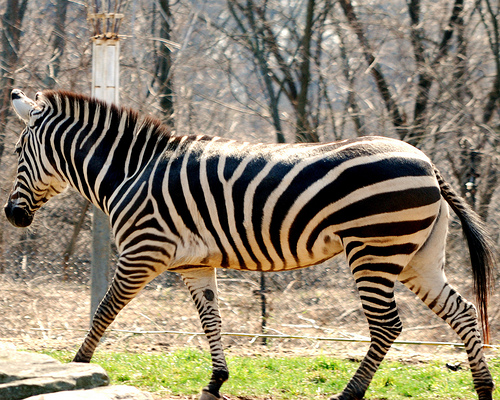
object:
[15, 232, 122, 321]
fencing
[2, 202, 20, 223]
snout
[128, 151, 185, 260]
stripe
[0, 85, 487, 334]
camera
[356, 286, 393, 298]
stripe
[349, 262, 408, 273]
black stripe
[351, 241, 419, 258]
stripe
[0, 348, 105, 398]
rock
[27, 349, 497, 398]
grass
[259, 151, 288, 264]
stripe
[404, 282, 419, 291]
stripe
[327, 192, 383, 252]
stripe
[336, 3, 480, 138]
trees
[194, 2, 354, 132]
trees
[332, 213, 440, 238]
black stripe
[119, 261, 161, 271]
black stripe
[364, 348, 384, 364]
black stripe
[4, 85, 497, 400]
zebra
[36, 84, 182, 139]
mane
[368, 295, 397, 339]
stripes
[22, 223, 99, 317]
chain link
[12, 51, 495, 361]
enclosure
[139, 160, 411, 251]
pattern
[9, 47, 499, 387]
zoo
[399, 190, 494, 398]
leg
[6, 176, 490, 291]
fence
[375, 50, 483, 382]
camera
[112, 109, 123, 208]
stripe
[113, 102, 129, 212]
stripe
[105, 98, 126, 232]
stripe